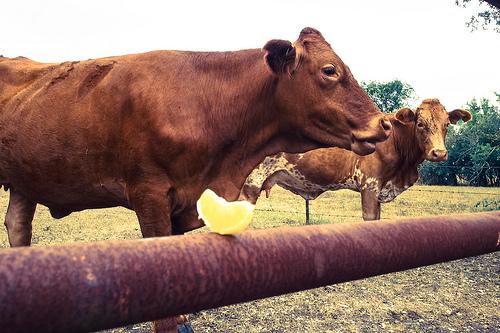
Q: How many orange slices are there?
A: One.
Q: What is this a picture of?
A: Cows.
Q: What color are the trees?
A: Green.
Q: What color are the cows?
A: Brown and white.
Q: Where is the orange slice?
A: The railing.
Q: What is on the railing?
A: Orange slice.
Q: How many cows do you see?
A: Two.